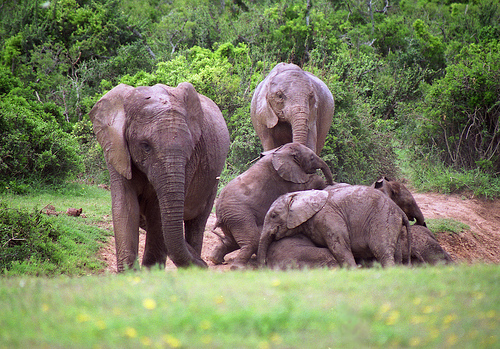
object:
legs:
[209, 209, 264, 269]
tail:
[211, 217, 229, 246]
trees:
[272, 1, 321, 59]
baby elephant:
[257, 179, 414, 266]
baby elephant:
[399, 225, 453, 265]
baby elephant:
[369, 176, 426, 223]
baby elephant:
[210, 142, 335, 272]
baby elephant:
[264, 232, 341, 270]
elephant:
[247, 60, 337, 182]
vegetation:
[3, 84, 81, 195]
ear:
[87, 81, 135, 180]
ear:
[176, 79, 203, 148]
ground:
[419, 172, 456, 189]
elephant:
[256, 183, 412, 267]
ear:
[252, 73, 281, 129]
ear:
[271, 148, 310, 183]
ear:
[285, 189, 330, 230]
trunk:
[287, 111, 310, 147]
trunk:
[318, 158, 335, 186]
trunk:
[257, 226, 277, 265]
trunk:
[408, 190, 427, 228]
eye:
[138, 138, 154, 152]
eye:
[275, 91, 285, 100]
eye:
[308, 153, 314, 161]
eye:
[270, 211, 279, 219]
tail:
[403, 212, 415, 265]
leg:
[223, 205, 259, 271]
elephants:
[87, 79, 229, 269]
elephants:
[250, 61, 334, 166]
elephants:
[205, 142, 345, 272]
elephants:
[369, 173, 425, 228]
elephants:
[387, 218, 456, 268]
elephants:
[263, 232, 340, 271]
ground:
[429, 197, 458, 212]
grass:
[3, 270, 500, 346]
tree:
[403, 39, 498, 146]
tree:
[365, 11, 447, 66]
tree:
[246, 4, 340, 66]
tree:
[114, 40, 258, 85]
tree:
[52, 3, 86, 127]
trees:
[424, 32, 500, 177]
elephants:
[86, 60, 448, 275]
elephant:
[257, 182, 416, 267]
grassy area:
[8, 262, 498, 347]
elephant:
[87, 82, 231, 271]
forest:
[7, 5, 483, 59]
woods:
[6, 91, 82, 184]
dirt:
[425, 189, 500, 262]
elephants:
[215, 145, 447, 266]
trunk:
[152, 163, 210, 270]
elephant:
[211, 140, 333, 271]